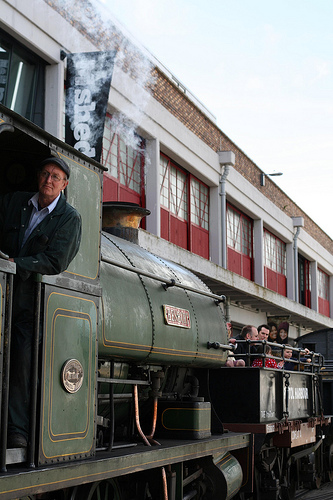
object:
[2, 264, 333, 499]
train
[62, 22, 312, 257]
station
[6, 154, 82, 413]
driver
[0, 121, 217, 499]
locomotive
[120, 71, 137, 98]
steam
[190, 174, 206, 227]
windows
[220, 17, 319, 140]
day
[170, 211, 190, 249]
panels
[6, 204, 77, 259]
jacket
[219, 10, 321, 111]
sky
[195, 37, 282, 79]
clouds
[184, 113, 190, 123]
bricks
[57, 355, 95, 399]
attachment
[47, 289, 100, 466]
door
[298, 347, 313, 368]
boy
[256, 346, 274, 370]
girl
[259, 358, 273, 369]
top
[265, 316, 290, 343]
banner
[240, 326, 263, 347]
man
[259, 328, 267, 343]
head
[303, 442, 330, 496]
wheel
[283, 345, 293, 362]
children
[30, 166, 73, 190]
glasses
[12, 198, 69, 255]
shirt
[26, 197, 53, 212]
collar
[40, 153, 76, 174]
hat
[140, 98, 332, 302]
building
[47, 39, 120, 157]
sign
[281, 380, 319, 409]
sign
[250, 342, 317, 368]
railing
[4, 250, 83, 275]
arm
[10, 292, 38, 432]
leg